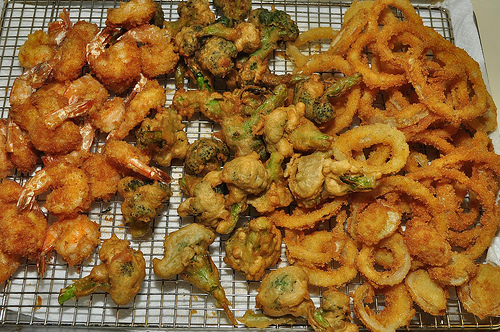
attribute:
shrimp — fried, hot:
[114, 21, 182, 80]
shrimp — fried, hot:
[83, 23, 146, 98]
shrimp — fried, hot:
[99, 137, 175, 188]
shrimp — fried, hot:
[15, 155, 94, 221]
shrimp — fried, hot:
[34, 208, 103, 279]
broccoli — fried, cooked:
[56, 232, 147, 310]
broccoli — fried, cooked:
[149, 220, 244, 328]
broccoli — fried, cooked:
[114, 175, 174, 241]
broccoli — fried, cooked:
[193, 16, 264, 56]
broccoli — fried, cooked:
[291, 72, 365, 125]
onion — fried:
[348, 276, 418, 332]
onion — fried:
[402, 261, 454, 318]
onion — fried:
[352, 230, 416, 290]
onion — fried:
[455, 259, 498, 321]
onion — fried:
[342, 27, 414, 90]